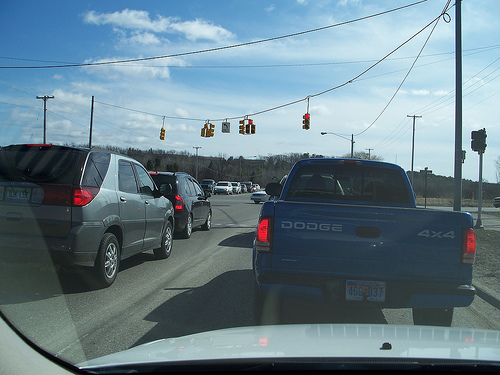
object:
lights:
[160, 126, 166, 140]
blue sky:
[1, 1, 499, 182]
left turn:
[245, 186, 281, 207]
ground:
[392, 180, 412, 210]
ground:
[401, 120, 441, 164]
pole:
[451, 0, 466, 211]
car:
[211, 180, 234, 196]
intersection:
[201, 182, 268, 238]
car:
[251, 158, 476, 326]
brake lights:
[256, 218, 270, 242]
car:
[1, 143, 175, 288]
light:
[73, 188, 93, 206]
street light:
[238, 119, 245, 135]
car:
[249, 190, 269, 203]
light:
[305, 113, 310, 118]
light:
[301, 124, 309, 130]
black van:
[144, 170, 213, 238]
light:
[302, 119, 310, 125]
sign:
[469, 127, 487, 152]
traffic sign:
[221, 121, 231, 133]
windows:
[117, 158, 139, 194]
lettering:
[281, 220, 342, 234]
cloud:
[0, 1, 498, 183]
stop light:
[302, 113, 310, 130]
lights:
[248, 119, 253, 124]